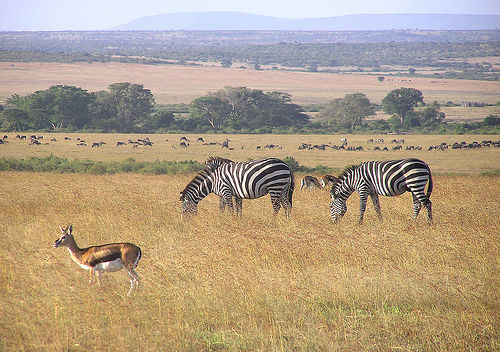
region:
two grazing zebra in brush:
[164, 150, 441, 225]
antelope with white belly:
[49, 222, 149, 297]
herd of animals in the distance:
[296, 130, 403, 161]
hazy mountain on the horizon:
[117, 8, 294, 38]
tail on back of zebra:
[420, 169, 442, 206]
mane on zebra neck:
[183, 160, 214, 192]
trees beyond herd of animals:
[190, 87, 300, 135]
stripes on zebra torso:
[364, 164, 406, 190]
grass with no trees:
[137, 69, 211, 84]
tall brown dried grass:
[195, 230, 310, 282]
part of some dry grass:
[260, 202, 353, 266]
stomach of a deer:
[99, 253, 123, 277]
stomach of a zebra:
[243, 172, 264, 197]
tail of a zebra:
[422, 176, 436, 196]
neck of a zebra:
[336, 181, 354, 199]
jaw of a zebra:
[336, 198, 348, 223]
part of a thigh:
[411, 182, 431, 203]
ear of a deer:
[64, 225, 75, 234]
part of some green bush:
[84, 155, 117, 175]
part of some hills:
[219, 1, 264, 22]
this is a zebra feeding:
[149, 154, 304, 218]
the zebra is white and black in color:
[170, 152, 303, 227]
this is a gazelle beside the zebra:
[47, 214, 171, 303]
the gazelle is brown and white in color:
[43, 214, 160, 314]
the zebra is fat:
[172, 150, 296, 226]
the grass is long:
[212, 249, 490, 350]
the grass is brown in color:
[210, 223, 480, 340]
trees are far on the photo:
[166, 93, 298, 125]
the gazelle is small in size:
[45, 225, 155, 311]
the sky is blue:
[0, 5, 398, 26]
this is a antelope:
[46, 217, 156, 301]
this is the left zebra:
[180, 137, 301, 233]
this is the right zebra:
[321, 138, 441, 234]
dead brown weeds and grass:
[238, 256, 298, 310]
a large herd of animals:
[28, 117, 472, 160]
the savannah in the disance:
[7, 59, 481, 130]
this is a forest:
[33, 84, 154, 137]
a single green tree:
[364, 71, 431, 139]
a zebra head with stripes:
[176, 172, 224, 229]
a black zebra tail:
[406, 155, 451, 217]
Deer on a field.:
[52, 222, 142, 299]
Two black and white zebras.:
[177, 155, 433, 227]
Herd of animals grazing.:
[1, 132, 498, 151]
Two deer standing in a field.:
[302, 172, 336, 190]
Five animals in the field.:
[52, 156, 476, 347]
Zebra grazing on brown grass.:
[178, 155, 295, 223]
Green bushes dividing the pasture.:
[0, 154, 185, 176]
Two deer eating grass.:
[302, 171, 335, 191]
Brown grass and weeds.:
[194, 230, 478, 290]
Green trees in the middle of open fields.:
[0, 80, 498, 132]